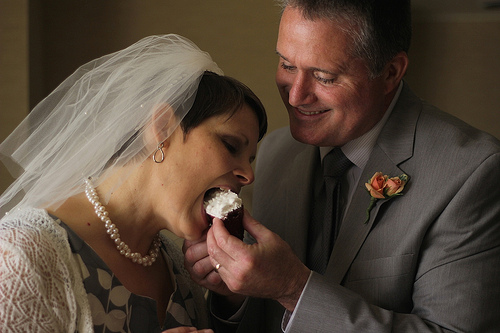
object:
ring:
[212, 260, 220, 274]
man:
[180, 0, 498, 332]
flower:
[363, 171, 409, 226]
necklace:
[81, 179, 165, 268]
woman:
[0, 70, 268, 333]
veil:
[0, 34, 226, 224]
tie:
[307, 146, 354, 275]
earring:
[151, 143, 166, 164]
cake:
[203, 186, 244, 227]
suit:
[204, 82, 500, 333]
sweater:
[0, 205, 204, 333]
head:
[97, 68, 268, 242]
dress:
[1, 211, 202, 332]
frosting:
[204, 188, 243, 220]